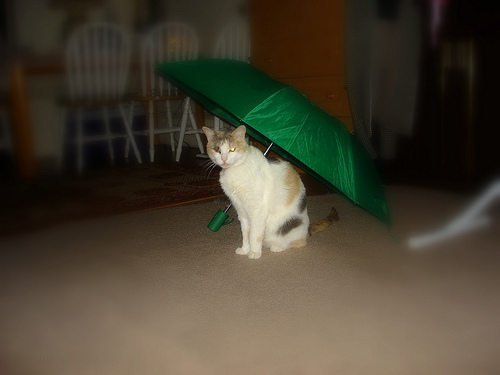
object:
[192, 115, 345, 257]
cat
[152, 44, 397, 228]
umbrella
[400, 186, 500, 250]
front leg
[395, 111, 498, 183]
board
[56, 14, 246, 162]
chairs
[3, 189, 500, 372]
rug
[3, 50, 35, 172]
end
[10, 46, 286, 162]
dining table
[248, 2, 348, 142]
chest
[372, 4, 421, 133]
jacket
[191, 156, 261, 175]
whiskers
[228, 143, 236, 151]
eye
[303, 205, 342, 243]
tail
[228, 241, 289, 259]
paws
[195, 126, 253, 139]
ears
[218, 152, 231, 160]
nose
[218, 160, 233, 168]
mouth